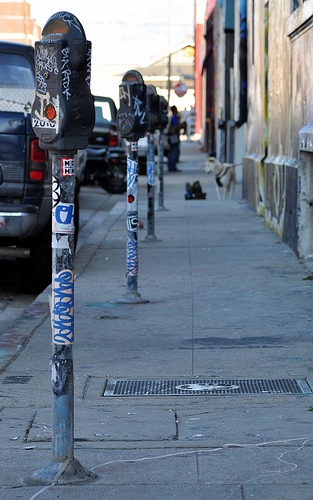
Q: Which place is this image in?
A: It is at the street.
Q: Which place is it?
A: It is a street.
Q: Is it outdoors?
A: Yes, it is outdoors.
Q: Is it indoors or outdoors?
A: It is outdoors.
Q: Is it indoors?
A: No, it is outdoors.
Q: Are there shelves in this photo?
A: No, there are no shelves.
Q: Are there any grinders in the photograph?
A: No, there are no grinders.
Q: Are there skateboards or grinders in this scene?
A: No, there are no grinders or skateboards.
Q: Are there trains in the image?
A: No, there are no trains.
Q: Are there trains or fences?
A: No, there are no trains or fences.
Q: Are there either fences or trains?
A: No, there are no trains or fences.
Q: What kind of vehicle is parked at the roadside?
A: The vehicle is a car.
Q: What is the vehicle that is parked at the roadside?
A: The vehicle is a car.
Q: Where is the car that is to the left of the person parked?
A: The car is parked at the roadside.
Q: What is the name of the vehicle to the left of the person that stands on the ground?
A: The vehicle is a car.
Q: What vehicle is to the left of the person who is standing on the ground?
A: The vehicle is a car.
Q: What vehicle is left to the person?
A: The vehicle is a car.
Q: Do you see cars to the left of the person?
A: Yes, there is a car to the left of the person.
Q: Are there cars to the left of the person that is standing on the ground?
A: Yes, there is a car to the left of the person.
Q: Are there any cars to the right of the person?
A: No, the car is to the left of the person.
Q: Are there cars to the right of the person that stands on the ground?
A: No, the car is to the left of the person.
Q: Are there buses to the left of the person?
A: No, there is a car to the left of the person.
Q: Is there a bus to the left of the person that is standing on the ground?
A: No, there is a car to the left of the person.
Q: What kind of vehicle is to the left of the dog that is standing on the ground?
A: The vehicle is a car.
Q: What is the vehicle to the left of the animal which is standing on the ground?
A: The vehicle is a car.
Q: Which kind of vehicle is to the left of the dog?
A: The vehicle is a car.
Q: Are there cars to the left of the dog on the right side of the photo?
A: Yes, there is a car to the left of the dog.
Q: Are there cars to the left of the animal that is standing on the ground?
A: Yes, there is a car to the left of the dog.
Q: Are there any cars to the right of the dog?
A: No, the car is to the left of the dog.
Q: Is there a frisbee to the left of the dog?
A: No, there is a car to the left of the dog.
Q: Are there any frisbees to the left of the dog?
A: No, there is a car to the left of the dog.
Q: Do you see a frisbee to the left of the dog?
A: No, there is a car to the left of the dog.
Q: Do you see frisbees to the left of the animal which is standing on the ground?
A: No, there is a car to the left of the dog.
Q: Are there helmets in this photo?
A: No, there are no helmets.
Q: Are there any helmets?
A: No, there are no helmets.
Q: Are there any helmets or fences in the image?
A: No, there are no helmets or fences.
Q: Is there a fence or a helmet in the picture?
A: No, there are no helmets or fences.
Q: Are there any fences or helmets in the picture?
A: No, there are no helmets or fences.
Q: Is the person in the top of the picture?
A: Yes, the person is in the top of the image.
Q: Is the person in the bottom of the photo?
A: No, the person is in the top of the image.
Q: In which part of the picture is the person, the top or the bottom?
A: The person is in the top of the image.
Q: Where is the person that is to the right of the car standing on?
A: The person is standing on the ground.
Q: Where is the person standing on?
A: The person is standing on the ground.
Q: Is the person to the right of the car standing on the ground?
A: Yes, the person is standing on the ground.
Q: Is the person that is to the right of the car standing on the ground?
A: Yes, the person is standing on the ground.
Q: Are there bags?
A: Yes, there is a bag.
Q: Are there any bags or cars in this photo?
A: Yes, there is a bag.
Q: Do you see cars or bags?
A: Yes, there is a bag.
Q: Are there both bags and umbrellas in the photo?
A: No, there is a bag but no umbrellas.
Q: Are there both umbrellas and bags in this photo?
A: No, there is a bag but no umbrellas.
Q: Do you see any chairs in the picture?
A: No, there are no chairs.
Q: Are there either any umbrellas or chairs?
A: No, there are no chairs or umbrellas.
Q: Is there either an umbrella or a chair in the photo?
A: No, there are no chairs or umbrellas.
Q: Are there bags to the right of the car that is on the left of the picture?
A: Yes, there is a bag to the right of the car.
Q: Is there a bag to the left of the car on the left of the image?
A: No, the bag is to the right of the car.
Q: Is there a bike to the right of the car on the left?
A: No, there is a bag to the right of the car.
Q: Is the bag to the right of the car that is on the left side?
A: Yes, the bag is to the right of the car.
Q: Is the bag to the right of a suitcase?
A: No, the bag is to the right of the car.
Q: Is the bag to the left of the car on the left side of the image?
A: No, the bag is to the right of the car.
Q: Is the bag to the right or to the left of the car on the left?
A: The bag is to the right of the car.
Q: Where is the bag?
A: The bag is on the ground.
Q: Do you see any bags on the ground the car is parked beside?
A: Yes, there is a bag on the ground.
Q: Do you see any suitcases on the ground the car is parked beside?
A: No, there is a bag on the ground.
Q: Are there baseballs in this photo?
A: No, there are no baseballs.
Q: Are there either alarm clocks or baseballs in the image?
A: No, there are no baseballs or alarm clocks.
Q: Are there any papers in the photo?
A: No, there are no papers.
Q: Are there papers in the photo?
A: No, there are no papers.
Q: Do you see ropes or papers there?
A: No, there are no papers or ropes.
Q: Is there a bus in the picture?
A: No, there are no buses.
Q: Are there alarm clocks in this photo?
A: No, there are no alarm clocks.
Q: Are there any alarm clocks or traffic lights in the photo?
A: No, there are no alarm clocks or traffic lights.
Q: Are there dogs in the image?
A: Yes, there is a dog.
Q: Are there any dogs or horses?
A: Yes, there is a dog.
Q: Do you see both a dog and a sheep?
A: No, there is a dog but no sheep.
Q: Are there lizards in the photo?
A: No, there are no lizards.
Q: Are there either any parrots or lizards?
A: No, there are no lizards or parrots.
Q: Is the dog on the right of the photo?
A: Yes, the dog is on the right of the image.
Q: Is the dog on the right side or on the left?
A: The dog is on the right of the image.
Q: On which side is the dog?
A: The dog is on the right of the image.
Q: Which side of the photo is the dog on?
A: The dog is on the right of the image.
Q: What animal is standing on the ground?
A: The animal is a dog.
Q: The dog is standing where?
A: The dog is standing on the ground.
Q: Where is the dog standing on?
A: The dog is standing on the ground.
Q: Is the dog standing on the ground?
A: Yes, the dog is standing on the ground.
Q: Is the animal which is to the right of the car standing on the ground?
A: Yes, the dog is standing on the ground.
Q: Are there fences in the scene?
A: No, there are no fences.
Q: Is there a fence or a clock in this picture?
A: No, there are no fences or clocks.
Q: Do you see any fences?
A: No, there are no fences.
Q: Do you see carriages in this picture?
A: No, there are no carriages.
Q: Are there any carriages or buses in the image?
A: No, there are no carriages or buses.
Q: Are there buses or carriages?
A: No, there are no carriages or buses.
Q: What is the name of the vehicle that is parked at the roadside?
A: The vehicle is a car.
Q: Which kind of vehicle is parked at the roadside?
A: The vehicle is a car.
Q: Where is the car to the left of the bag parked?
A: The car is parked at the roadside.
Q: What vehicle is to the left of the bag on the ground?
A: The vehicle is a car.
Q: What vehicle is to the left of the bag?
A: The vehicle is a car.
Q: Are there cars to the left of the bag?
A: Yes, there is a car to the left of the bag.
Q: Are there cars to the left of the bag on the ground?
A: Yes, there is a car to the left of the bag.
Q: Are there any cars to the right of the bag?
A: No, the car is to the left of the bag.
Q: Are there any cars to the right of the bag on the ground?
A: No, the car is to the left of the bag.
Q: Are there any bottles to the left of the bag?
A: No, there is a car to the left of the bag.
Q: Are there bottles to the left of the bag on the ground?
A: No, there is a car to the left of the bag.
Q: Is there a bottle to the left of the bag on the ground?
A: No, there is a car to the left of the bag.